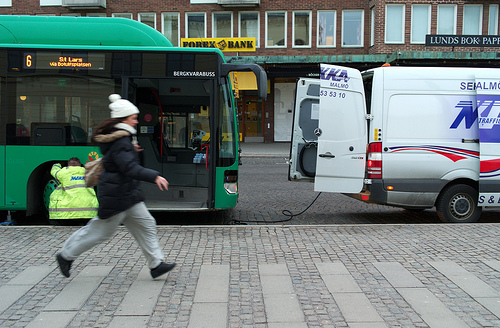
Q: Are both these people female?
A: No, they are both male and female.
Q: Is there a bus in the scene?
A: Yes, there is a bus.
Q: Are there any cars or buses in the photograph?
A: Yes, there is a bus.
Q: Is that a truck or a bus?
A: That is a bus.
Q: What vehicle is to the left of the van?
A: The vehicle is a bus.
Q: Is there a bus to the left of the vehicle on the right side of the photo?
A: Yes, there is a bus to the left of the van.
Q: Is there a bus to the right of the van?
A: No, the bus is to the left of the van.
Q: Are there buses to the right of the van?
A: No, the bus is to the left of the van.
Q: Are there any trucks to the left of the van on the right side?
A: No, there is a bus to the left of the van.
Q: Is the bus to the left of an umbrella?
A: No, the bus is to the left of the van.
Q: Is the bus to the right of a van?
A: No, the bus is to the left of a van.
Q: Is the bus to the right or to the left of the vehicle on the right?
A: The bus is to the left of the van.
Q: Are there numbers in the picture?
A: Yes, there are numbers.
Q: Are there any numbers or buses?
A: Yes, there are numbers.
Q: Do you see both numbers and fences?
A: No, there are numbers but no fences.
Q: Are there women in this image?
A: Yes, there is a woman.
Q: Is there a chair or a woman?
A: Yes, there is a woman.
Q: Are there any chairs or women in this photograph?
A: Yes, there is a woman.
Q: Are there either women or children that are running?
A: Yes, the woman is running.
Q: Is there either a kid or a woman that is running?
A: Yes, the woman is running.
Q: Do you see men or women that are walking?
A: Yes, the woman is walking.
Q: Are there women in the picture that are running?
A: Yes, there is a woman that is running.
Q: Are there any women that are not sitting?
A: Yes, there is a woman that is running.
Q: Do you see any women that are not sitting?
A: Yes, there is a woman that is running .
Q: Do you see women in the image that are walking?
A: Yes, there is a woman that is walking.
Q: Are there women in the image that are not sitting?
A: Yes, there is a woman that is walking.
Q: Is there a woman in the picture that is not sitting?
A: Yes, there is a woman that is walking.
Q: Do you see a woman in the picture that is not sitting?
A: Yes, there is a woman that is walking .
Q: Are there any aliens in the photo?
A: No, there are no aliens.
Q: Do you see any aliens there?
A: No, there are no aliens.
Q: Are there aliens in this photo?
A: No, there are no aliens.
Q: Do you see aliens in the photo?
A: No, there are no aliens.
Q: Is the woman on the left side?
A: Yes, the woman is on the left of the image.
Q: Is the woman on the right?
A: No, the woman is on the left of the image.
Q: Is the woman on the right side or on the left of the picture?
A: The woman is on the left of the image.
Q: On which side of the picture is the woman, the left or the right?
A: The woman is on the left of the image.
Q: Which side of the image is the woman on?
A: The woman is on the left of the image.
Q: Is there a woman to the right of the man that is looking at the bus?
A: Yes, there is a woman to the right of the man.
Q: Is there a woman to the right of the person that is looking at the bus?
A: Yes, there is a woman to the right of the man.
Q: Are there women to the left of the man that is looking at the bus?
A: No, the woman is to the right of the man.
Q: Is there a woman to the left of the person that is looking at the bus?
A: No, the woman is to the right of the man.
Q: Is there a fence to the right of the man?
A: No, there is a woman to the right of the man.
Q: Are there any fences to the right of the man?
A: No, there is a woman to the right of the man.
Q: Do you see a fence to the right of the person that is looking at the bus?
A: No, there is a woman to the right of the man.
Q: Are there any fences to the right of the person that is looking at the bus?
A: No, there is a woman to the right of the man.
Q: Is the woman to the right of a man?
A: Yes, the woman is to the right of a man.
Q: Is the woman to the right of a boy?
A: No, the woman is to the right of a man.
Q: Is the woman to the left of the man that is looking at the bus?
A: No, the woman is to the right of the man.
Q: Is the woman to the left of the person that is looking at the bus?
A: No, the woman is to the right of the man.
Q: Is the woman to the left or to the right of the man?
A: The woman is to the right of the man.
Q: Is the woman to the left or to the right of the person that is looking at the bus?
A: The woman is to the right of the man.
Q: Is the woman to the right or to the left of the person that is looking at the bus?
A: The woman is to the right of the man.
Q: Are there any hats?
A: Yes, there is a hat.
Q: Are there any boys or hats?
A: Yes, there is a hat.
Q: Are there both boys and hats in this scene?
A: No, there is a hat but no boys.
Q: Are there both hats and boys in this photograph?
A: No, there is a hat but no boys.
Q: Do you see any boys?
A: No, there are no boys.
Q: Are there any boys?
A: No, there are no boys.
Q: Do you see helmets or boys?
A: No, there are no boys or helmets.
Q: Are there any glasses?
A: No, there are no glasses.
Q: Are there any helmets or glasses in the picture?
A: No, there are no glasses or helmets.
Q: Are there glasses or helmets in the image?
A: No, there are no glasses or helmets.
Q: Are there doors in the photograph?
A: Yes, there are doors.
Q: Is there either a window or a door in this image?
A: Yes, there are doors.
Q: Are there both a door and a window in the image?
A: Yes, there are both a door and a window.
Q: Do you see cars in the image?
A: No, there are no cars.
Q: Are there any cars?
A: No, there are no cars.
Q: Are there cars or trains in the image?
A: No, there are no cars or trains.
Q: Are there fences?
A: No, there are no fences.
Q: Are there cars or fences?
A: No, there are no fences or cars.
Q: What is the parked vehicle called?
A: The vehicle is a van.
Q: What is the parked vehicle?
A: The vehicle is a van.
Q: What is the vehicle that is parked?
A: The vehicle is a van.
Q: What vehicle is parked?
A: The vehicle is a van.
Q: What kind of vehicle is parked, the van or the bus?
A: The van is parked.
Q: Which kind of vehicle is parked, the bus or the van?
A: The van is parked.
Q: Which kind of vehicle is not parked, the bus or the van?
A: The bus is not parked.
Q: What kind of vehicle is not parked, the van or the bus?
A: The bus is not parked.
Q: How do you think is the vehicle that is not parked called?
A: The vehicle is a bus.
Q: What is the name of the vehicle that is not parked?
A: The vehicle is a bus.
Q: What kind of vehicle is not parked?
A: The vehicle is a bus.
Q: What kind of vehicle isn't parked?
A: The vehicle is a bus.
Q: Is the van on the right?
A: Yes, the van is on the right of the image.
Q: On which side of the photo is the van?
A: The van is on the right of the image.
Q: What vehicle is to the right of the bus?
A: The vehicle is a van.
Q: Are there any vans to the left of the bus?
A: No, the van is to the right of the bus.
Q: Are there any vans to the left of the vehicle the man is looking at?
A: No, the van is to the right of the bus.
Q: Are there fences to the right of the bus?
A: No, there is a van to the right of the bus.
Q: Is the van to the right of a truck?
A: No, the van is to the right of a bus.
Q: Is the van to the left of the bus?
A: No, the van is to the right of the bus.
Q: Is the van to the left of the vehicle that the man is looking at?
A: No, the van is to the right of the bus.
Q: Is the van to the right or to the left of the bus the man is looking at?
A: The van is to the right of the bus.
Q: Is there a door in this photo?
A: Yes, there is a door.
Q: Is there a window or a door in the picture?
A: Yes, there is a door.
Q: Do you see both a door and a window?
A: Yes, there are both a door and a window.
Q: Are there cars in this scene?
A: No, there are no cars.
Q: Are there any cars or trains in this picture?
A: No, there are no cars or trains.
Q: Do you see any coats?
A: Yes, there is a coat.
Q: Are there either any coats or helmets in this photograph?
A: Yes, there is a coat.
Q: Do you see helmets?
A: No, there are no helmets.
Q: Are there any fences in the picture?
A: No, there are no fences.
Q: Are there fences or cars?
A: No, there are no fences or cars.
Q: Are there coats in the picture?
A: Yes, there is a coat.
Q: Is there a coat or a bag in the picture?
A: Yes, there is a coat.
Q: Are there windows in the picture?
A: Yes, there are windows.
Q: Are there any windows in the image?
A: Yes, there are windows.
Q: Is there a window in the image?
A: Yes, there are windows.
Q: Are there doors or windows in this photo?
A: Yes, there are windows.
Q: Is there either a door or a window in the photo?
A: Yes, there are windows.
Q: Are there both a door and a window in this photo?
A: Yes, there are both a window and a door.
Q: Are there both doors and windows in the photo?
A: Yes, there are both windows and a door.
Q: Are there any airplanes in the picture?
A: No, there are no airplanes.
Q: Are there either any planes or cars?
A: No, there are no planes or cars.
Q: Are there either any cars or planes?
A: No, there are no planes or cars.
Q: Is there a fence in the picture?
A: No, there are no fences.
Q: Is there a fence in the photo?
A: No, there are no fences.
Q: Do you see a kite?
A: No, there are no kites.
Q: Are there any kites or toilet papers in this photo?
A: No, there are no kites or toilet papers.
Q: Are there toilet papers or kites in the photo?
A: No, there are no kites or toilet papers.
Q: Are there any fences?
A: No, there are no fences.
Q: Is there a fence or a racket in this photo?
A: No, there are no fences or rackets.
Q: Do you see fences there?
A: No, there are no fences.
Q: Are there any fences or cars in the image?
A: No, there are no fences or cars.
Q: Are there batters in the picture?
A: No, there are no batters.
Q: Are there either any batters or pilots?
A: No, there are no batters or pilots.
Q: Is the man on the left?
A: Yes, the man is on the left of the image.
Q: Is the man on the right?
A: No, the man is on the left of the image.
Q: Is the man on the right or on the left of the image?
A: The man is on the left of the image.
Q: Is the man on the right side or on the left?
A: The man is on the left of the image.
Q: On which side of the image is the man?
A: The man is on the left of the image.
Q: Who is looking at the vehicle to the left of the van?
A: The man is looking at the bus.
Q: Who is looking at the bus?
A: The man is looking at the bus.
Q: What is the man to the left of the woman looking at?
A: The man is looking at the bus.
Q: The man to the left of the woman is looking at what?
A: The man is looking at the bus.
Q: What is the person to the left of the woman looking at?
A: The man is looking at the bus.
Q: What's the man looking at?
A: The man is looking at the bus.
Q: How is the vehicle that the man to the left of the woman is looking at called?
A: The vehicle is a bus.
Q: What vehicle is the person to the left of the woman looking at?
A: The man is looking at the bus.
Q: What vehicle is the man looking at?
A: The man is looking at the bus.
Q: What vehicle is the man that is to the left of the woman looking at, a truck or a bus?
A: The man is looking at a bus.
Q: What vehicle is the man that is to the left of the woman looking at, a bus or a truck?
A: The man is looking at a bus.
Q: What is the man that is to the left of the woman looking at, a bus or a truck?
A: The man is looking at a bus.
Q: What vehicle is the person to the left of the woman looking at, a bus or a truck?
A: The man is looking at a bus.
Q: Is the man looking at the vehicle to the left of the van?
A: Yes, the man is looking at the bus.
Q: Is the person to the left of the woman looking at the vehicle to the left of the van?
A: Yes, the man is looking at the bus.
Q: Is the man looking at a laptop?
A: No, the man is looking at the bus.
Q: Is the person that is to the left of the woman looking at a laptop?
A: No, the man is looking at the bus.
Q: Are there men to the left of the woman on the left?
A: Yes, there is a man to the left of the woman.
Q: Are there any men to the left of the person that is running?
A: Yes, there is a man to the left of the woman.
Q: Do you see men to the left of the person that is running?
A: Yes, there is a man to the left of the woman.